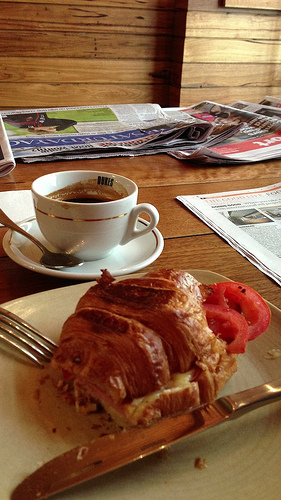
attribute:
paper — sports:
[184, 99, 278, 162]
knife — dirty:
[7, 412, 188, 481]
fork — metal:
[62, 429, 227, 466]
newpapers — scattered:
[11, 109, 266, 164]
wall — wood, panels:
[2, 3, 247, 97]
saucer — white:
[1, 212, 164, 277]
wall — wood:
[2, 4, 277, 129]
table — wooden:
[5, 158, 278, 498]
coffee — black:
[48, 184, 111, 203]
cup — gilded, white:
[31, 169, 158, 259]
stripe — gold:
[41, 206, 132, 224]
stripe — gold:
[9, 217, 161, 268]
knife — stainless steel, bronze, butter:
[9, 382, 279, 494]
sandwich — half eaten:
[43, 268, 268, 421]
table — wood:
[171, 218, 194, 257]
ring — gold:
[51, 212, 84, 223]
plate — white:
[36, 300, 55, 325]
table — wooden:
[167, 212, 188, 267]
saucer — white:
[17, 213, 158, 264]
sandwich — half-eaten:
[68, 279, 235, 407]